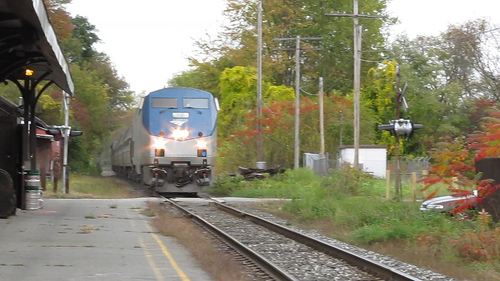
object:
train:
[96, 85, 222, 193]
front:
[148, 87, 221, 193]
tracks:
[48, 196, 404, 203]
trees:
[297, 1, 401, 92]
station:
[0, 0, 76, 219]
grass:
[347, 218, 436, 244]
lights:
[154, 127, 209, 150]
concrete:
[32, 210, 144, 275]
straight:
[187, 211, 249, 248]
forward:
[258, 231, 305, 257]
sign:
[394, 66, 410, 120]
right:
[339, 141, 372, 153]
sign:
[61, 90, 70, 111]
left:
[83, 120, 108, 142]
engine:
[151, 168, 210, 188]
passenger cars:
[110, 128, 132, 173]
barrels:
[24, 169, 43, 210]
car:
[419, 190, 480, 213]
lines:
[122, 199, 192, 280]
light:
[378, 118, 424, 142]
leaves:
[268, 100, 295, 116]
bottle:
[38, 188, 44, 207]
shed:
[335, 145, 388, 179]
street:
[47, 196, 168, 262]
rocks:
[222, 217, 244, 229]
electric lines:
[294, 31, 300, 171]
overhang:
[0, 0, 76, 98]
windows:
[182, 97, 210, 109]